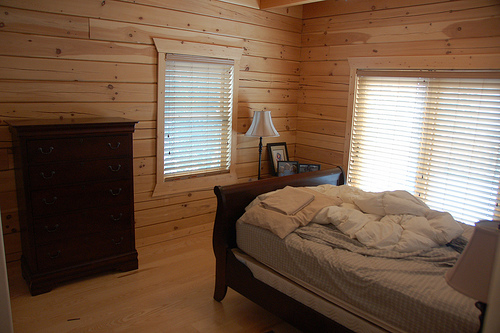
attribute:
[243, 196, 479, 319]
sheets — white, striped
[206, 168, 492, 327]
bed — messy, brown, wooden, unmade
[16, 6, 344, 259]
walls — wood, wood paneled, wooden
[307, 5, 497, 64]
walls — wood, wood paneled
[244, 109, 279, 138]
lamp shade — white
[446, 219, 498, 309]
lamp shade — white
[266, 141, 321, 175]
frames — black, rectangle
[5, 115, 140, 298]
dresser — dark brown, wooden, brown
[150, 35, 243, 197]
window — wood framed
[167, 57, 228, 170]
blinds — white, horizontal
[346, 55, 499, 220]
window — wood framed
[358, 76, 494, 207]
blinds — white, horizontal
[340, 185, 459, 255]
comforter — white, crumpled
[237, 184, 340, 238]
pillow — beige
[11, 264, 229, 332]
floor — wooden, wood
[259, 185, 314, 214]
pillow case — folded